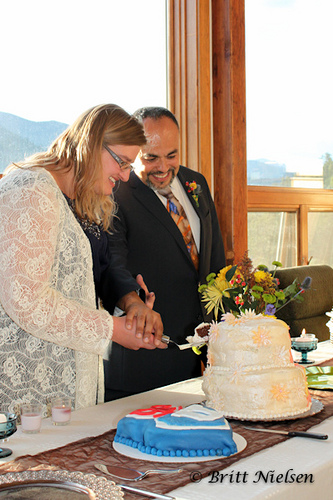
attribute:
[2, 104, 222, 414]
couple — smiling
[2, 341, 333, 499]
on the table — burgandy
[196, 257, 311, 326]
bouquet of flowers — colorful arrangement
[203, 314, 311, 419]
wedding cake — white, floral, flowery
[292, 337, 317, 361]
candle holder — blue green color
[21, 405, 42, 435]
two candle holders — clear glass